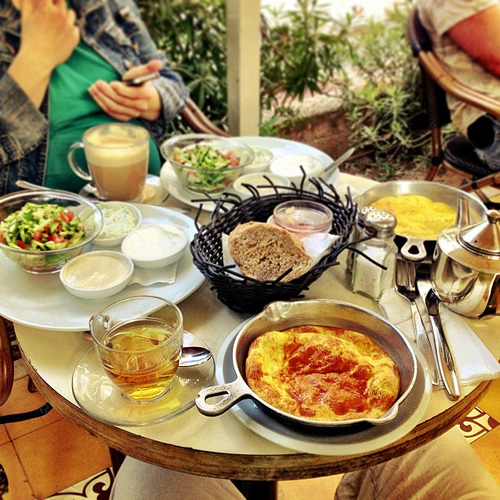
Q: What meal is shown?
A: Brunch.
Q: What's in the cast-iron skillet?
A: Food.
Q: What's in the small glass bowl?
A: Salad.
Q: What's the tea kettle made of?
A: Metal.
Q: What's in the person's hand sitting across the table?
A: Cell Phone.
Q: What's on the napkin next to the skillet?
A: Silverware.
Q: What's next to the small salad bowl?
A: Three white bowls.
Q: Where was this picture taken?
A: In a restaurant.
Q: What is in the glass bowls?
A: Salad.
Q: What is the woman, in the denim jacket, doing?
A: Checking her cell phone.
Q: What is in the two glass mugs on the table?
A: Tea and coffee.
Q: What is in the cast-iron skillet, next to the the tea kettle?
A: Cooked eggs.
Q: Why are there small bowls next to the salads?
A: They are condiments for the salad.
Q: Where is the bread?
A: In a black wicker basket.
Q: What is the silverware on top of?
A: A white napkin.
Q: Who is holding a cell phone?
A: A woman.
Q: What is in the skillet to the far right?
A: Eggs.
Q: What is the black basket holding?
A: Bread.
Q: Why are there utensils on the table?
A: The people are eating a meal.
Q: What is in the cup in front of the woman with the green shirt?
A: A cup of coffee.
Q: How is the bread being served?
A: In a basket.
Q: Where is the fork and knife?
A: On a napkin.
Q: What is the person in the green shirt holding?
A: A cell phone.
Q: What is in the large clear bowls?
A: Salad.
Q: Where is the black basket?
A: Middle of the table.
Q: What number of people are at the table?
A: 2.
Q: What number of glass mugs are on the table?
A: 2.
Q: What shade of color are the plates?
A: White.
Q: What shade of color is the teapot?
A: Silver.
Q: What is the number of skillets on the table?
A: 2.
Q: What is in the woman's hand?
A: Cell phone.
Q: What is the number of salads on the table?
A: 2.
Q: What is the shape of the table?
A: Round.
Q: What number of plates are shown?
A: 4.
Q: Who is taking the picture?
A: The waitress.